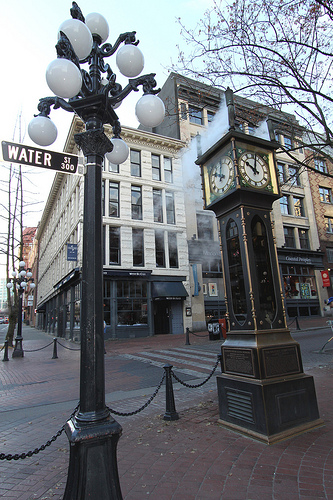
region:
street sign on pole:
[4, 141, 101, 179]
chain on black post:
[138, 371, 170, 419]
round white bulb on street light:
[131, 89, 168, 130]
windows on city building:
[121, 166, 175, 245]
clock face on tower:
[235, 147, 281, 189]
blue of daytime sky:
[135, 1, 179, 30]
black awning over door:
[151, 280, 189, 304]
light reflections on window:
[286, 195, 308, 223]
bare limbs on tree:
[238, 30, 290, 66]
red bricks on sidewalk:
[252, 443, 318, 483]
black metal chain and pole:
[116, 350, 220, 447]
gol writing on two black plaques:
[208, 337, 303, 378]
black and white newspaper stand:
[176, 311, 224, 356]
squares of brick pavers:
[149, 446, 316, 498]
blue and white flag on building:
[37, 231, 78, 276]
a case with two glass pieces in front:
[202, 203, 289, 340]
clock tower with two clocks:
[185, 135, 280, 390]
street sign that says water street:
[1, 144, 84, 180]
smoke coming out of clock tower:
[140, 86, 281, 280]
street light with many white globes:
[0, 239, 52, 385]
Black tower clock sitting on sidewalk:
[189, 124, 324, 449]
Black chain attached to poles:
[3, 341, 239, 465]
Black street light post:
[46, 127, 136, 495]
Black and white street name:
[0, 136, 84, 174]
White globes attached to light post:
[20, 3, 168, 165]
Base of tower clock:
[205, 367, 324, 452]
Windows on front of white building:
[86, 120, 193, 275]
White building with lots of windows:
[31, 108, 198, 333]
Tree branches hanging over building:
[173, 1, 329, 140]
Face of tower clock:
[238, 147, 270, 189]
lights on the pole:
[40, 19, 155, 153]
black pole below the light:
[52, 229, 143, 328]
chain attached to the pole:
[128, 381, 170, 424]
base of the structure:
[209, 385, 329, 448]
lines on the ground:
[161, 437, 231, 495]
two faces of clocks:
[190, 144, 271, 202]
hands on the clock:
[212, 157, 231, 184]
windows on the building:
[134, 187, 178, 237]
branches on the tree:
[240, 31, 301, 79]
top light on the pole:
[85, 10, 117, 40]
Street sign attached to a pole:
[0, 136, 86, 175]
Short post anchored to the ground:
[159, 357, 181, 424]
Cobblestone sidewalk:
[144, 437, 247, 487]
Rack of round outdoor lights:
[12, 7, 165, 172]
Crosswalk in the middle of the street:
[130, 335, 249, 389]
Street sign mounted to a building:
[64, 239, 80, 263]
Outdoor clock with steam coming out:
[184, 82, 285, 211]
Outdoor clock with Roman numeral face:
[234, 142, 275, 195]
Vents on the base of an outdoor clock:
[219, 383, 258, 427]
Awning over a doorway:
[150, 277, 189, 307]